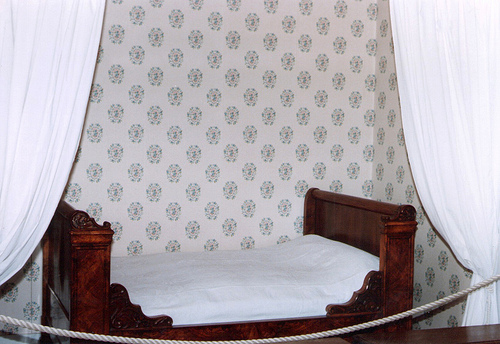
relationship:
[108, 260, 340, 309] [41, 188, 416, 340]
sheet on bed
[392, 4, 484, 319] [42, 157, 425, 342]
drape in front of bed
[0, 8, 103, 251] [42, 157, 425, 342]
drape in front of bed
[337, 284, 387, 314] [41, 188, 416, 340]
carving on bed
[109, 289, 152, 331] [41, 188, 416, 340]
carving on bed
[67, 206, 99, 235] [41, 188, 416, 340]
carving on bed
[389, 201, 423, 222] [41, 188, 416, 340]
carving on bed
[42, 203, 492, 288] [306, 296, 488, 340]
furniture behind rope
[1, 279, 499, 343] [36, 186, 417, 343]
rope hanging in front of furniture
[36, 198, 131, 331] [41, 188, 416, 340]
footboard adorning bed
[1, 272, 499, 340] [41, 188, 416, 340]
rope hanging in front of bed